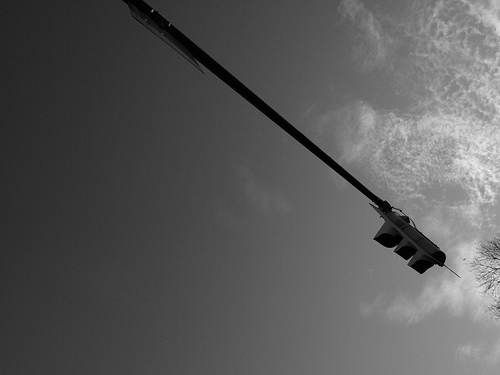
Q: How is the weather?
A: It is cloudy.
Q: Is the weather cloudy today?
A: Yes, it is cloudy.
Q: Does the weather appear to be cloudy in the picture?
A: Yes, it is cloudy.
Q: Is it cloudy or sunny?
A: It is cloudy.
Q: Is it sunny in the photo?
A: No, it is cloudy.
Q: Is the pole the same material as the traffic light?
A: Yes, both the pole and the traffic light are made of metal.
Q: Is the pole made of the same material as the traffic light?
A: Yes, both the pole and the traffic light are made of metal.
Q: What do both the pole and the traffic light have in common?
A: The material, both the pole and the traffic light are metallic.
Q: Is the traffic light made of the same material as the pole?
A: Yes, both the traffic light and the pole are made of metal.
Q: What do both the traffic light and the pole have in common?
A: The material, both the traffic light and the pole are metallic.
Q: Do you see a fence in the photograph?
A: No, there are no fences.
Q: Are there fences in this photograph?
A: No, there are no fences.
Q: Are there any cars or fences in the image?
A: No, there are no fences or cars.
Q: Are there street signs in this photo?
A: Yes, there is a street sign.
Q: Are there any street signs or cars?
A: Yes, there is a street sign.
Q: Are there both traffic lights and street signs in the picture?
A: Yes, there are both a street sign and a traffic light.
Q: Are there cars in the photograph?
A: No, there are no cars.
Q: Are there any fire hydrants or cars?
A: No, there are no cars or fire hydrants.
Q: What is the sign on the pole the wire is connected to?
A: The sign is a street sign.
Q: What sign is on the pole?
A: The sign is a street sign.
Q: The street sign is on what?
A: The street sign is on the pole.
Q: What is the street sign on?
A: The street sign is on the pole.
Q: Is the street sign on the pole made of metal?
A: Yes, the street sign is on the pole.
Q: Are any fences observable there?
A: No, there are no fences.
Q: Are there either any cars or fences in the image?
A: No, there are no fences or cars.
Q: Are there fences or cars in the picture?
A: No, there are no fences or cars.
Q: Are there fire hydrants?
A: No, there are no fire hydrants.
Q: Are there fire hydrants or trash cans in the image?
A: No, there are no fire hydrants or trash cans.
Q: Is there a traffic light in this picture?
A: Yes, there is a traffic light.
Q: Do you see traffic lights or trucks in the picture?
A: Yes, there is a traffic light.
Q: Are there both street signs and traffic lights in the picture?
A: Yes, there are both a traffic light and a street sign.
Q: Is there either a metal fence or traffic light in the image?
A: Yes, there is a metal traffic light.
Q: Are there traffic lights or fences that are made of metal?
A: Yes, the traffic light is made of metal.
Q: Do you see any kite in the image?
A: No, there are no kites.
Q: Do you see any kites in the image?
A: No, there are no kites.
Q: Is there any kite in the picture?
A: No, there are no kites.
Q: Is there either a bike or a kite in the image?
A: No, there are no kites or bikes.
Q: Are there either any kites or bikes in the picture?
A: No, there are no kites or bikes.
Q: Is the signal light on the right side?
A: Yes, the signal light is on the right of the image.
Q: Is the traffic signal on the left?
A: No, the traffic signal is on the right of the image.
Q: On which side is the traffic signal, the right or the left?
A: The traffic signal is on the right of the image.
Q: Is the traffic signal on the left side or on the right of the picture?
A: The traffic signal is on the right of the image.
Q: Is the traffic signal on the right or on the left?
A: The traffic signal is on the right of the image.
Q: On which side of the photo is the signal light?
A: The signal light is on the right of the image.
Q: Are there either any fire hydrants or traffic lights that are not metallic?
A: No, there is a traffic light but it is metallic.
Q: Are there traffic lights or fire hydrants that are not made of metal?
A: No, there is a traffic light but it is made of metal.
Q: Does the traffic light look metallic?
A: Yes, the traffic light is metallic.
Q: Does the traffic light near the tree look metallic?
A: Yes, the signal light is metallic.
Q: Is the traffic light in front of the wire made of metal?
A: Yes, the traffic light is made of metal.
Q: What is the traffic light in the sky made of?
A: The traffic signal is made of metal.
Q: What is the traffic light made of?
A: The traffic signal is made of metal.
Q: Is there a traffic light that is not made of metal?
A: No, there is a traffic light but it is made of metal.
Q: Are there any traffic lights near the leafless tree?
A: Yes, there is a traffic light near the tree.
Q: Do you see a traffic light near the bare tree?
A: Yes, there is a traffic light near the tree.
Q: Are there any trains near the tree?
A: No, there is a traffic light near the tree.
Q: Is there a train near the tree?
A: No, there is a traffic light near the tree.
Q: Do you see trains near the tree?
A: No, there is a traffic light near the tree.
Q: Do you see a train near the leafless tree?
A: No, there is a traffic light near the tree.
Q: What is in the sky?
A: The signal light is in the sky.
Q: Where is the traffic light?
A: The traffic light is in the sky.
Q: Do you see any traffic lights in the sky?
A: Yes, there is a traffic light in the sky.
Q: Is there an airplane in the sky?
A: No, there is a traffic light in the sky.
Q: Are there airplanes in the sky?
A: No, there is a traffic light in the sky.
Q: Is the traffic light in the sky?
A: Yes, the traffic light is in the sky.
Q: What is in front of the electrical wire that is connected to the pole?
A: The traffic light is in front of the wire.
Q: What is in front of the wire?
A: The traffic light is in front of the wire.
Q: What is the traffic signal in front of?
A: The traffic signal is in front of the wire.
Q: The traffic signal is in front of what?
A: The traffic signal is in front of the wire.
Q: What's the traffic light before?
A: The traffic signal is in front of the wire.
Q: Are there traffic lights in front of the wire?
A: Yes, there is a traffic light in front of the wire.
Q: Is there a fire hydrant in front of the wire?
A: No, there is a traffic light in front of the wire.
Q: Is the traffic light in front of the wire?
A: Yes, the traffic light is in front of the wire.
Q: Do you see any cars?
A: No, there are no cars.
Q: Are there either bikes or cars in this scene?
A: No, there are no cars or bikes.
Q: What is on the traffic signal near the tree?
A: The wire is on the traffic signal.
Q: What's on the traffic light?
A: The wire is on the traffic signal.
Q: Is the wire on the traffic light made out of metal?
A: Yes, the wire is on the signal light.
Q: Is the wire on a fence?
A: No, the wire is on the signal light.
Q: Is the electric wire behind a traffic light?
A: Yes, the wire is behind a traffic light.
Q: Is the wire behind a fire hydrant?
A: No, the wire is behind a traffic light.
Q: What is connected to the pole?
A: The wire is connected to the pole.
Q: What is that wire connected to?
A: The wire is connected to the pole.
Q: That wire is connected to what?
A: The wire is connected to the pole.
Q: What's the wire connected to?
A: The wire is connected to the pole.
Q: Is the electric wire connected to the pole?
A: Yes, the wire is connected to the pole.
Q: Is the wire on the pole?
A: Yes, the wire is on the pole.